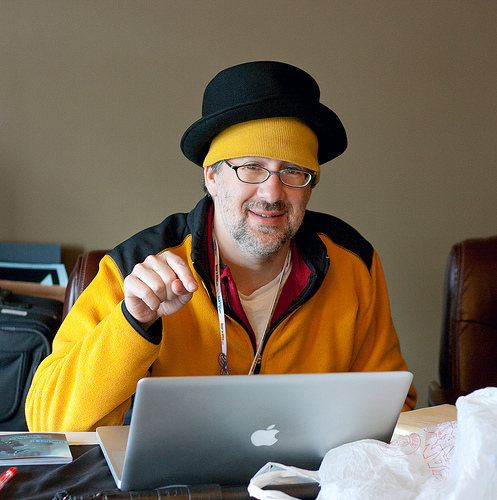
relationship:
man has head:
[22, 61, 417, 433] [203, 116, 320, 269]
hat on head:
[178, 61, 349, 166] [203, 116, 320, 269]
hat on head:
[202, 117, 321, 186] [203, 116, 320, 269]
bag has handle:
[1, 288, 62, 432] [0, 290, 31, 311]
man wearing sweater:
[22, 61, 417, 433] [25, 194, 417, 432]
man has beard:
[22, 61, 417, 433] [218, 183, 309, 261]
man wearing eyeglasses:
[22, 61, 417, 433] [224, 159, 317, 188]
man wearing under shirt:
[22, 61, 417, 433] [238, 251, 291, 350]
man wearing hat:
[22, 61, 417, 433] [178, 61, 349, 166]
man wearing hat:
[22, 61, 417, 433] [202, 117, 321, 186]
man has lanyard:
[22, 61, 417, 433] [211, 228, 293, 375]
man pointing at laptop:
[22, 61, 417, 433] [94, 370, 415, 491]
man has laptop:
[22, 61, 417, 433] [94, 370, 415, 491]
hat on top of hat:
[178, 61, 349, 166] [202, 117, 321, 186]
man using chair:
[22, 61, 417, 433] [61, 248, 112, 323]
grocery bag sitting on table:
[247, 387, 497, 499] [1, 402, 456, 499]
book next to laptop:
[0, 432, 73, 467] [94, 370, 415, 491]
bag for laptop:
[1, 288, 62, 432] [94, 370, 415, 491]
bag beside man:
[1, 288, 62, 432] [22, 61, 417, 433]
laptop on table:
[94, 370, 415, 491] [1, 402, 456, 499]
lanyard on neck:
[211, 228, 293, 375] [214, 207, 291, 267]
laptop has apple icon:
[94, 370, 415, 491] [251, 423, 282, 448]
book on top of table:
[0, 432, 73, 467] [1, 402, 456, 499]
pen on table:
[1, 467, 20, 490] [1, 402, 456, 499]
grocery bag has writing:
[247, 387, 497, 499] [379, 419, 458, 482]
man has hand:
[22, 61, 417, 433] [122, 251, 198, 324]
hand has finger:
[122, 251, 198, 324] [164, 251, 200, 293]